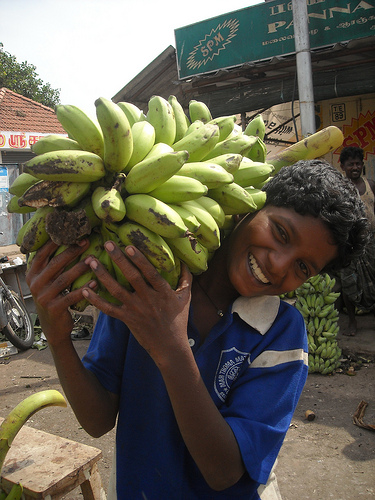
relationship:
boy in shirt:
[27, 161, 371, 500] [74, 294, 308, 498]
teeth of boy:
[246, 259, 272, 286] [27, 161, 371, 500]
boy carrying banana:
[16, 63, 350, 468] [94, 96, 133, 171]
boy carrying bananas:
[27, 161, 371, 500] [59, 96, 270, 213]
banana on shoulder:
[209, 130, 263, 163] [94, 263, 206, 346]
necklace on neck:
[189, 272, 225, 320] [196, 254, 237, 314]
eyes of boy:
[272, 217, 313, 279] [27, 161, 371, 500]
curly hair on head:
[257, 160, 374, 270] [229, 163, 366, 306]